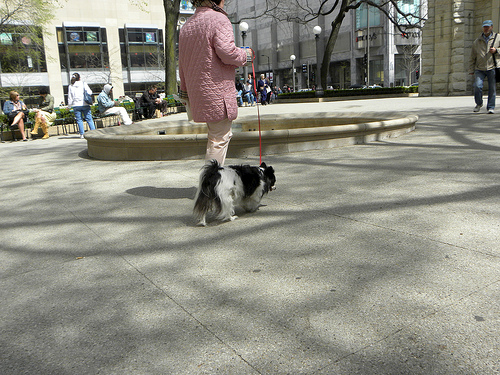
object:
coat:
[175, 0, 250, 122]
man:
[468, 20, 500, 115]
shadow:
[125, 184, 196, 200]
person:
[178, 0, 254, 166]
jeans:
[72, 106, 95, 135]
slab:
[115, 209, 500, 374]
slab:
[0, 252, 262, 374]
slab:
[298, 171, 499, 259]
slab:
[34, 167, 221, 245]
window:
[56, 26, 110, 70]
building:
[0, 0, 196, 113]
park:
[0, 13, 499, 375]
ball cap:
[482, 19, 493, 27]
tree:
[279, 0, 428, 97]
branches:
[271, 2, 334, 23]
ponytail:
[71, 76, 75, 84]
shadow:
[260, 105, 500, 176]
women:
[3, 91, 30, 141]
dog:
[193, 158, 277, 226]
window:
[118, 27, 165, 70]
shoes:
[473, 103, 483, 112]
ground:
[0, 95, 499, 374]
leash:
[249, 48, 262, 165]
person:
[97, 84, 134, 125]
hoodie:
[97, 84, 115, 113]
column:
[447, 0, 476, 96]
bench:
[10, 107, 67, 141]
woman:
[67, 72, 94, 137]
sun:
[2, 92, 484, 371]